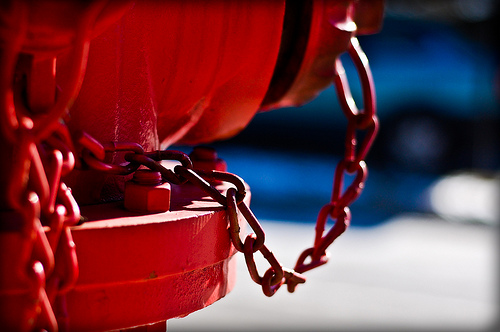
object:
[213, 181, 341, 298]
chain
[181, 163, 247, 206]
link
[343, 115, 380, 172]
link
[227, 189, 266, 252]
link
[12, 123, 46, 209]
link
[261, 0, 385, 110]
water spout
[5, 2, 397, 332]
fire hydrant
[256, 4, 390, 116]
cap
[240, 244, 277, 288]
link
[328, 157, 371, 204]
link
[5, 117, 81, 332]
chain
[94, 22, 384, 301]
chain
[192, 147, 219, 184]
screw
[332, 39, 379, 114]
link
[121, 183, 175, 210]
fastener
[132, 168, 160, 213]
screw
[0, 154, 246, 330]
base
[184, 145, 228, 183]
nuts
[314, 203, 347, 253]
link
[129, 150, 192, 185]
link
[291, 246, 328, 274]
link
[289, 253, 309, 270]
edge